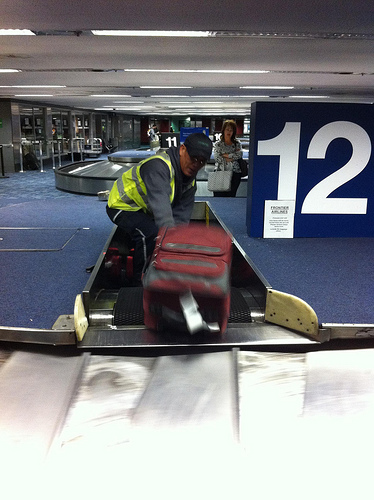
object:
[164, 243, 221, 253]
stripe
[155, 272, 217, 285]
stripe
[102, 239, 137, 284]
suitcase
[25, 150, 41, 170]
suitcase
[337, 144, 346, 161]
ground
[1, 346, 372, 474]
belt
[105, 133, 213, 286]
worker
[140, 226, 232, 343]
luggage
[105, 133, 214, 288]
man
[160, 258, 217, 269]
black stripe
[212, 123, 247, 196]
woman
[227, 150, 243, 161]
arm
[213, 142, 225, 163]
arm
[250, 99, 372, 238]
sign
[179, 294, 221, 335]
tag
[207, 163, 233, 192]
bag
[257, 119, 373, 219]
number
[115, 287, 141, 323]
belt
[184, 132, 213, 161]
cap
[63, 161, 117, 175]
belt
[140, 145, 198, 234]
shirt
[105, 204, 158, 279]
pants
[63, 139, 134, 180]
belt peice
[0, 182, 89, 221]
floor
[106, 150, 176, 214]
vest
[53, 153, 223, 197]
carosuel